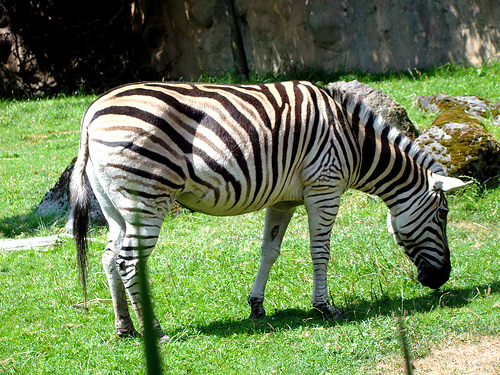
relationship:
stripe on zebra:
[292, 80, 301, 158] [69, 82, 466, 338]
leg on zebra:
[305, 180, 340, 317] [69, 82, 466, 338]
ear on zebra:
[435, 174, 473, 193] [69, 82, 466, 338]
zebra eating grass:
[69, 82, 466, 338] [376, 337, 498, 374]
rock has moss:
[408, 94, 498, 183] [430, 99, 480, 125]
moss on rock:
[430, 99, 480, 125] [408, 94, 498, 183]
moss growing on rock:
[430, 99, 480, 125] [408, 94, 498, 183]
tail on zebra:
[69, 119, 91, 304] [69, 82, 466, 338]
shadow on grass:
[205, 283, 499, 336] [376, 337, 498, 374]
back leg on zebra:
[100, 190, 174, 339] [69, 82, 466, 338]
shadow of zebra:
[205, 283, 499, 336] [69, 82, 466, 338]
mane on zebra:
[334, 89, 443, 175] [69, 82, 466, 338]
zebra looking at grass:
[69, 82, 466, 338] [376, 337, 498, 374]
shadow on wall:
[12, 0, 170, 86] [1, 0, 498, 99]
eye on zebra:
[441, 209, 449, 216] [69, 82, 466, 338]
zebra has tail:
[69, 82, 466, 338] [69, 119, 91, 304]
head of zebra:
[387, 173, 453, 287] [69, 82, 466, 338]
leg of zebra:
[246, 200, 294, 319] [69, 82, 466, 338]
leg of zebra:
[305, 180, 340, 317] [69, 82, 466, 338]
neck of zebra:
[348, 107, 434, 207] [69, 82, 466, 338]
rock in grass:
[408, 94, 498, 183] [376, 337, 498, 374]